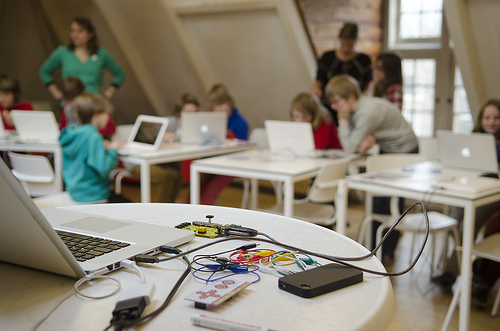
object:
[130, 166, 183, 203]
pants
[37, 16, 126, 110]
girl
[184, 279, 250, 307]
controller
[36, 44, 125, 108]
shirt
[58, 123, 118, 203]
shirt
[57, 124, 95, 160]
hood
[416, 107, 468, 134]
ground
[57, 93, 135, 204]
boy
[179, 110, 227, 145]
laptop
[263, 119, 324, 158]
laptop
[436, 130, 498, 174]
laptop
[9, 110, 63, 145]
laptop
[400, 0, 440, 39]
paned windows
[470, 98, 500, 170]
people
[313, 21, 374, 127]
people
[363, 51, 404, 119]
people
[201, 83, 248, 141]
people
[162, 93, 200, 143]
people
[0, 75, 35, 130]
people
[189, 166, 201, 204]
legs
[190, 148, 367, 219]
table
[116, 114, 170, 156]
computer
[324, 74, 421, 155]
boy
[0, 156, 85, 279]
cover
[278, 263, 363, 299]
phone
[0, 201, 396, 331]
table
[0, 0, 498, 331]
room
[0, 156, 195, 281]
computer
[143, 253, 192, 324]
wires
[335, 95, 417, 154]
sweater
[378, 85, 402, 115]
shirt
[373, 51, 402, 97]
hair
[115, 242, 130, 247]
buttons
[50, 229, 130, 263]
keyboard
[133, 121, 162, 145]
monitor face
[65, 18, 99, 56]
hair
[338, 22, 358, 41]
hair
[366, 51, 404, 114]
student